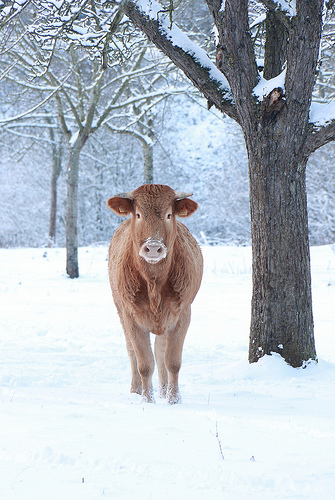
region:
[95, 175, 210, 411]
large brown cow in snow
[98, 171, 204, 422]
large brown cow near tree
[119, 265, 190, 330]
thick brown cow fur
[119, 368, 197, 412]
cow feet in snow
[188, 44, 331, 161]
tree branches with snow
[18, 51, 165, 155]
leafless brown snowy trees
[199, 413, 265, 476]
twigs poking up through snow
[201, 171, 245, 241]
snowy brambles in background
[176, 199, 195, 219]
cattle tag in cow's ears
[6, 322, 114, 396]
cow tracks in the snow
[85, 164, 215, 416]
Brown cow standing in the snow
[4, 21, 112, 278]
Tree with no leaves with snow covered branches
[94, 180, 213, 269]
Head of a brown cow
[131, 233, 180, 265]
Brown cows nose with snow on it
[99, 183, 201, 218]
Brown cows ears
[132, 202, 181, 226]
Brown cows eyes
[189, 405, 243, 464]
Twig sticking out of the snow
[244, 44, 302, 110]
Snow accumulated in the fork of a tree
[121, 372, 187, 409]
Brown cows feet in the snow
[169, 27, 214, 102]
Snow on the top side of a tree branch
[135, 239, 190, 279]
Cow has brown nose.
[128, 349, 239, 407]
Cow has brown legs.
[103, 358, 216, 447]
Cow is standing in snow.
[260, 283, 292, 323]
Tree trunk is grayish brown.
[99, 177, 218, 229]
Cow has brown furry ears.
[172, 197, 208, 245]
Cow has tag on ear.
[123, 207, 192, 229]
Cow has brown eyes.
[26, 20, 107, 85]
Snow covering tree branches.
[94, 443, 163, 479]
Snow on ground is white.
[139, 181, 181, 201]
Top of cow's head is brown.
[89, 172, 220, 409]
A cow standing in snow.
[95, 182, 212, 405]
A brown cow.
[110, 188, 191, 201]
A set of horns on a cow's head.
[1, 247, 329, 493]
Snow covered ground.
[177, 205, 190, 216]
A yellow tag on cow's left ear.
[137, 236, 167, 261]
A cow's nose covered in ice.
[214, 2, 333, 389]
A tree trunk covered in bark.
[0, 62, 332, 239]
A snow covered forest.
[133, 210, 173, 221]
Black eyes on a cow.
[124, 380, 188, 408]
Cow hooves in the snow.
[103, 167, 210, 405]
A cow in the snow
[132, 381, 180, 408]
Snow on the feet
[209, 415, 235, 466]
A weed in the snow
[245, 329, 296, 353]
SNow on the tree trunk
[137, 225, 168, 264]
Snow on the snout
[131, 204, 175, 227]
The eyes of the coy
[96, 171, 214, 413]
the brown cow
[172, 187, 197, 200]
The horn of the cow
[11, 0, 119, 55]
Snow covered branchs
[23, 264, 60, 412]
Snow on the ground